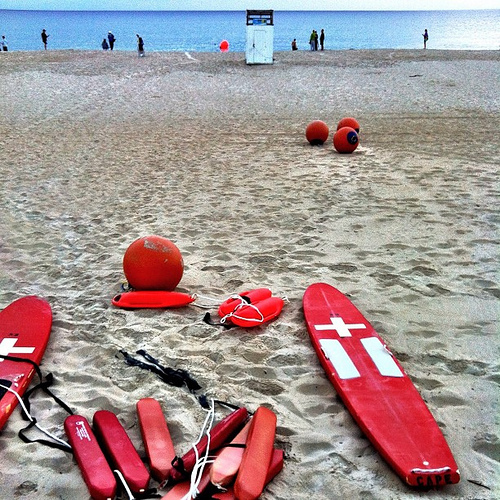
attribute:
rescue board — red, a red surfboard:
[302, 281, 461, 491]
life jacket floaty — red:
[111, 291, 197, 310]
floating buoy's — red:
[218, 288, 286, 331]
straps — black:
[118, 346, 239, 416]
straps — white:
[189, 397, 216, 500]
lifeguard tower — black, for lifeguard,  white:
[246, 8, 277, 65]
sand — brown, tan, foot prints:
[1, 51, 498, 499]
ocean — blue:
[1, 6, 247, 29]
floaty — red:
[66, 414, 117, 499]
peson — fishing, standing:
[420, 26, 432, 51]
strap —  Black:
[203, 288, 285, 330]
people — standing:
[1, 28, 147, 55]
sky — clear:
[1, 1, 498, 15]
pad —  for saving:
[218, 283, 281, 340]